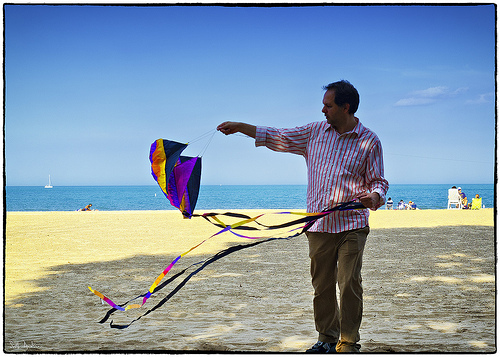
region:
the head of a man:
[315, 73, 362, 123]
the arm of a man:
[241, 116, 311, 153]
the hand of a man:
[215, 115, 240, 136]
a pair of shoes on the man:
[305, 327, 365, 348]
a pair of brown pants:
[301, 215, 371, 340]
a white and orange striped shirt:
[250, 110, 390, 232]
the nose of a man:
[316, 101, 326, 111]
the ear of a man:
[340, 95, 350, 111]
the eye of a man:
[322, 99, 336, 110]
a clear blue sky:
[2, 3, 495, 186]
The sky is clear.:
[380, 44, 494, 176]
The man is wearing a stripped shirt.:
[252, 91, 407, 316]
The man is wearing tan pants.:
[259, 64, 401, 330]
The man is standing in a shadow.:
[55, 92, 497, 354]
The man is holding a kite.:
[120, 74, 423, 247]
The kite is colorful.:
[130, 128, 221, 219]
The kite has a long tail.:
[134, 130, 364, 304]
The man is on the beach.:
[227, 72, 411, 354]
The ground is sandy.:
[47, 223, 132, 274]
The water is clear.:
[46, 187, 163, 207]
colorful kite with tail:
[85, 97, 257, 354]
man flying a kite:
[12, 67, 404, 355]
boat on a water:
[34, 151, 94, 216]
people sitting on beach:
[370, 170, 481, 252]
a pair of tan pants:
[262, 238, 384, 338]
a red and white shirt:
[266, 108, 376, 233]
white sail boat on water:
[0, 152, 66, 197]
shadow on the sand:
[15, 218, 252, 353]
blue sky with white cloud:
[398, 70, 498, 125]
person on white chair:
[428, 172, 468, 238]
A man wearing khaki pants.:
[272, 217, 352, 345]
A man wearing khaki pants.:
[281, 238, 322, 335]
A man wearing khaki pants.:
[314, 214, 369, 331]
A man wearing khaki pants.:
[285, 247, 315, 301]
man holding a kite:
[151, 103, 254, 223]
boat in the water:
[34, 165, 68, 192]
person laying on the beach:
[70, 198, 107, 222]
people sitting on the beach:
[447, 185, 496, 226]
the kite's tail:
[71, 196, 381, 311]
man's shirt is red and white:
[278, 111, 396, 244]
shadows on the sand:
[27, 242, 292, 354]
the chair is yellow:
[469, 192, 486, 216]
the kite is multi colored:
[135, 128, 240, 234]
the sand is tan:
[22, 215, 177, 252]